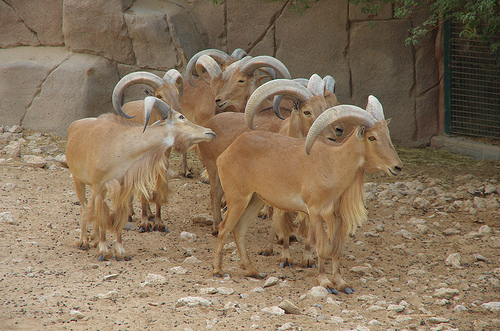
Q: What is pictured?
A: Billy goats.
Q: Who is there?
A: No one.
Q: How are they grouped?
A: Together.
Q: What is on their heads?
A: Horns.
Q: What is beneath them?
A: Rocks.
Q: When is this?
A: Daytime.